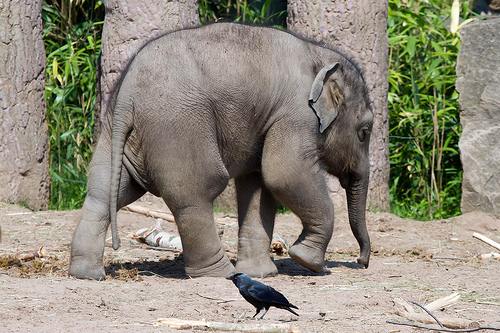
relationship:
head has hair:
[315, 46, 376, 183] [319, 44, 371, 114]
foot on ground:
[183, 246, 236, 278] [2, 202, 498, 331]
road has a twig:
[0, 211, 495, 329] [387, 300, 498, 333]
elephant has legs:
[70, 23, 372, 276] [69, 141, 146, 280]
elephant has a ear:
[70, 23, 372, 276] [310, 61, 343, 132]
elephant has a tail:
[70, 23, 372, 276] [111, 73, 134, 249]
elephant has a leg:
[70, 23, 372, 276] [134, 124, 238, 277]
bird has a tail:
[228, 273, 299, 321] [276, 292, 299, 317]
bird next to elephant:
[228, 273, 299, 321] [70, 23, 372, 276]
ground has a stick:
[2, 202, 498, 331] [386, 300, 499, 331]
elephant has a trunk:
[70, 23, 372, 276] [341, 178, 371, 267]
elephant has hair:
[70, 23, 372, 276] [319, 44, 371, 114]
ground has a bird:
[2, 202, 498, 331] [228, 273, 299, 321]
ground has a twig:
[2, 202, 498, 331] [387, 300, 498, 333]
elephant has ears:
[70, 23, 372, 276] [310, 61, 345, 132]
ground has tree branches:
[2, 202, 498, 331] [388, 300, 498, 332]